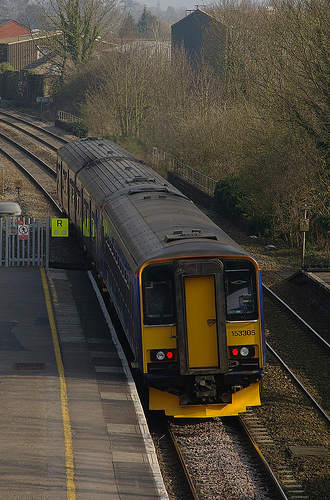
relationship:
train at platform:
[64, 129, 271, 447] [20, 263, 127, 493]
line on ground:
[36, 336, 90, 468] [27, 330, 156, 437]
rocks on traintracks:
[194, 437, 257, 497] [159, 426, 308, 499]